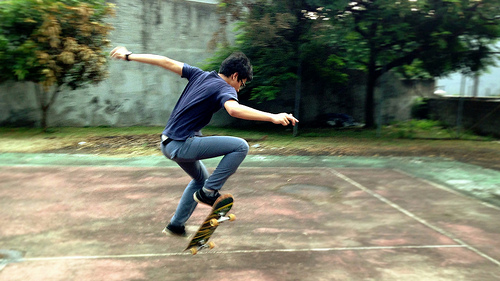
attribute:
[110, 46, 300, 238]
man — skateboarding, jumping, riding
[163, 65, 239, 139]
shirt — blue, dark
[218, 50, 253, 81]
hair — brown, black, short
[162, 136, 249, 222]
pants — green, blue, long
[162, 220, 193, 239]
shoe — black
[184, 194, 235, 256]
skateboard — black, yellow , one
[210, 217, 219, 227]
wheel — tan, yellow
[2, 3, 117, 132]
tree — green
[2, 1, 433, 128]
wall — gray, dirty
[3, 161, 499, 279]
concrete — brown, orange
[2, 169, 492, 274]
court — brown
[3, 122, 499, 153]
grass — behind, growing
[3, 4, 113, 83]
leaves — green